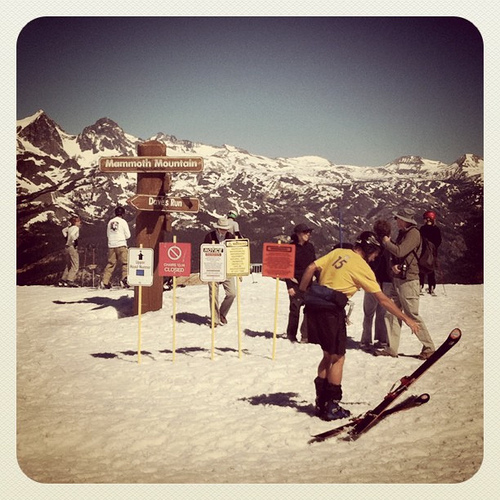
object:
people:
[61, 213, 81, 286]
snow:
[15, 279, 483, 481]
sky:
[15, 16, 483, 171]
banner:
[261, 242, 295, 280]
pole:
[271, 278, 279, 363]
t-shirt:
[104, 216, 130, 249]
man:
[96, 205, 132, 290]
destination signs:
[96, 155, 204, 177]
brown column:
[130, 137, 172, 320]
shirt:
[310, 248, 380, 300]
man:
[296, 230, 424, 419]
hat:
[389, 206, 420, 228]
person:
[204, 217, 236, 326]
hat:
[207, 215, 237, 232]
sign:
[224, 238, 252, 278]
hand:
[403, 317, 422, 334]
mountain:
[14, 101, 484, 286]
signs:
[199, 242, 227, 282]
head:
[391, 206, 413, 232]